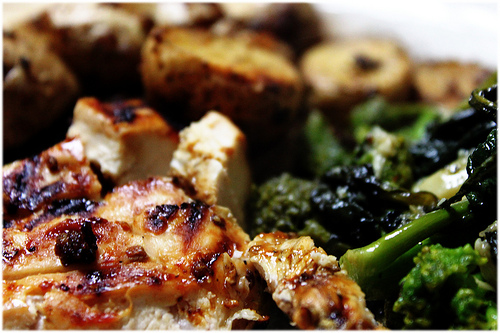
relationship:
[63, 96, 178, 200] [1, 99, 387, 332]
chunk of chicken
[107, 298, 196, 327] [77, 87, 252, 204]
interior of chicken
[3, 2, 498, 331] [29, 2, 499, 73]
food on plate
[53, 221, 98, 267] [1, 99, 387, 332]
dark spot on chicken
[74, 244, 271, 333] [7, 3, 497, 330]
food dish on plate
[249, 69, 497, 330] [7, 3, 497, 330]
green vegetables on plate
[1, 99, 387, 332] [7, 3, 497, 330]
chicken on plate